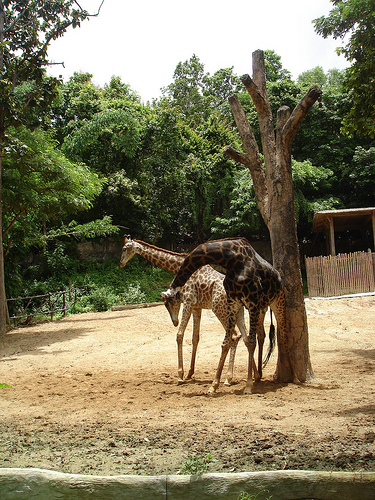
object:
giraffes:
[160, 237, 301, 394]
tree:
[222, 49, 322, 385]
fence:
[304, 248, 375, 297]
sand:
[0, 296, 375, 475]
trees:
[313, 0, 375, 148]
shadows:
[313, 349, 374, 417]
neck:
[136, 238, 188, 274]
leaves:
[340, 127, 346, 137]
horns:
[160, 292, 167, 297]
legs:
[244, 305, 260, 394]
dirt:
[0, 426, 375, 475]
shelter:
[313, 208, 375, 257]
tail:
[263, 308, 275, 368]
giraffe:
[120, 234, 260, 395]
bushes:
[3, 252, 174, 327]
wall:
[0, 470, 375, 500]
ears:
[167, 292, 170, 295]